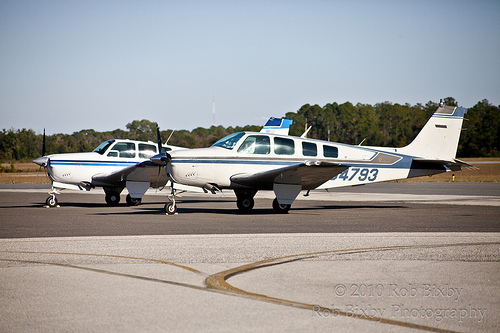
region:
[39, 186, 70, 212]
small front tire on back airplane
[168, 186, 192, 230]
small front tire on front airplane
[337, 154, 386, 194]
number 4793 on back of plane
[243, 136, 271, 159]
pilot window on front plane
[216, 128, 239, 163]
windshield on front of front plane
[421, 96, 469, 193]
back tail wing on end of plane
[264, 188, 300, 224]
black left tire of front plane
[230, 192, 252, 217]
black right tire of front plane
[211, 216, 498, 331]
circular pattern on ground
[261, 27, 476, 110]
clear light blue sky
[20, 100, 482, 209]
two blue and white airplanes on a tarmat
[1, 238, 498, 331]
the runway traffic lines painted on the ground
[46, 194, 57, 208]
front wheel of the plane in the back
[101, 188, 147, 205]
back wheels on the plane in the back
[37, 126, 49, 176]
propeller on the plane in the back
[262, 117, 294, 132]
tail wing on the plane in the back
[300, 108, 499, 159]
trees in the back behind both planes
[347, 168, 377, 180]
partial number on plane in the front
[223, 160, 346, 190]
wing on the plane in the front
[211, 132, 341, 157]
windows on the plane in the front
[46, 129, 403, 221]
two airplanes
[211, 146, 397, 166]
airplane has a blue stripe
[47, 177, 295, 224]
wheels are on the ground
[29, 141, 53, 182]
propeller has a silver tip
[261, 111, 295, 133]
blue on the tail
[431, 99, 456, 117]
silver on the tail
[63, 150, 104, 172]
airplane has two blue stripes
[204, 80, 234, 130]
tower behind the trees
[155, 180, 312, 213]
shadows on the tarmac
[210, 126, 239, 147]
airplane windshield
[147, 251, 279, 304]
curved brown line on the ground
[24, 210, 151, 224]
gray color on the runway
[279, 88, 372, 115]
top of tall green trees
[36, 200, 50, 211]
yellow barriers holding the plane's wheel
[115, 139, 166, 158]
shine of plane's window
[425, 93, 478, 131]
blue and gray color on wing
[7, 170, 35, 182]
parched brown grass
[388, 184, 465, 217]
white runway on the tarmac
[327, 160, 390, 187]
letters on side of plane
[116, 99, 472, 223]
small blue and white plane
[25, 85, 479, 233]
two planes on a landing lane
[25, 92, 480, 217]
planes are white and blue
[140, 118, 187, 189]
a propeller in front of plane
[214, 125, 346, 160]
four windows on side of plane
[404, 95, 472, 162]
vertical stabilizer is white and blue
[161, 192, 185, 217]
front wheel of plane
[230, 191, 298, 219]
back wheels of plane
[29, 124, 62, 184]
a propeller in front a plane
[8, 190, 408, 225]
shadows cast on ground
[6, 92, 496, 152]
trees on back of planes